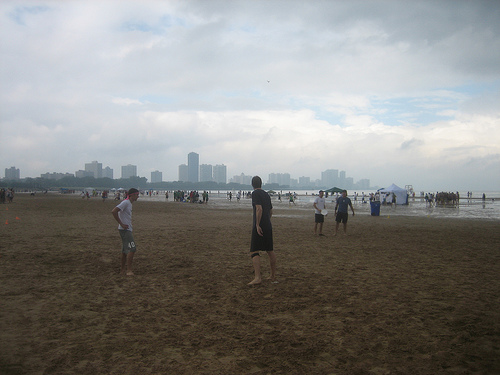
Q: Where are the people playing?
A: The beach.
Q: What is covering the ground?
A: Sand.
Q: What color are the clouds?
A: Gray.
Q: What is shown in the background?
A: Buildings.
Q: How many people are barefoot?
A: 3.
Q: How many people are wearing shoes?
A: 1.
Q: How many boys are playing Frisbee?
A: 4.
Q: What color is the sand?
A: Brown.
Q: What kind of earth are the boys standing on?
A: Sand.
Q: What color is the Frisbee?
A: White.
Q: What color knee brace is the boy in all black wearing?
A: Black.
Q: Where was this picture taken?
A: The beach.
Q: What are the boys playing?
A: Frisbee.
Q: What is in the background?
A: A city.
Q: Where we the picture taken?
A: On a beach.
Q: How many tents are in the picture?
A: 2.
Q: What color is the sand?
A: Brown.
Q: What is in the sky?
A: Clouds.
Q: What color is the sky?
A: Blue.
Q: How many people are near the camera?
A: 2.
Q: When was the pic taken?
A: During the day.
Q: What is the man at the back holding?
A: Freebee.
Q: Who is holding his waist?
A: The man on the left.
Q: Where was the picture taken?
A: At the beach.